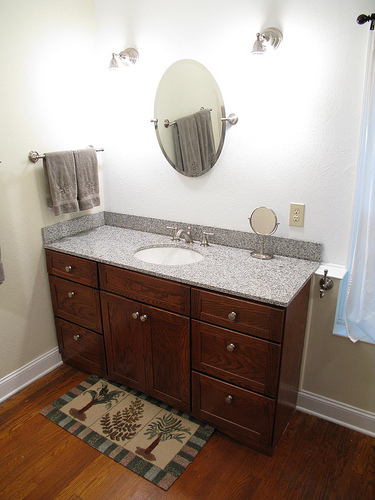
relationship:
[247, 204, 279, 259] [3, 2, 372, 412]
mirror on wall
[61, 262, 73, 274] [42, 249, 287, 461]
knob on cabinet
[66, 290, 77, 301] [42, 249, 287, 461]
knob on cabinet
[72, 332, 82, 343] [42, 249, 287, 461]
knob on cabinet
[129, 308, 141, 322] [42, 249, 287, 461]
knob on cabinet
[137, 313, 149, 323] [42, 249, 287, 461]
knob on cabinet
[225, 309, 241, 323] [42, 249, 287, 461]
knob on cabinet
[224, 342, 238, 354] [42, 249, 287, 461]
knob on cabinet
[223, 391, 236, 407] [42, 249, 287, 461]
knob on cabinet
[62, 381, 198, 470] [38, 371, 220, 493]
pattern on rug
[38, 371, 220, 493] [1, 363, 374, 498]
rug on floor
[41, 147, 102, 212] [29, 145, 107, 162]
towels on rack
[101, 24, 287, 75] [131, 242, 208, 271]
lights above sink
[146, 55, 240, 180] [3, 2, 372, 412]
mirror hanging on wall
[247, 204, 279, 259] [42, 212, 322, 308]
mirror on counter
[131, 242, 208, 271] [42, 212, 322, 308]
sink in countertop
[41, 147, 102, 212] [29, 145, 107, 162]
towels hanging on rack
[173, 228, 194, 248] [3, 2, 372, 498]
faucet in bathroom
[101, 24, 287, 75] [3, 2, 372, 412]
lights mounted to wall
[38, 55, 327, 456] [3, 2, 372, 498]
vanity in bathroom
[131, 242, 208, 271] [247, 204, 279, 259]
sink under mirror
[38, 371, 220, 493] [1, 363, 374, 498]
mat on floor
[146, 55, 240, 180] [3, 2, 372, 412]
mirror on wall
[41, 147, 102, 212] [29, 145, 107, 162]
towels on holder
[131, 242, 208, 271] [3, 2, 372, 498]
sink in bathroom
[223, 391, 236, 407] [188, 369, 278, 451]
knob on drawer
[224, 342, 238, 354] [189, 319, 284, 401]
knob on drawer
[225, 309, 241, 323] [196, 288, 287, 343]
knob on drawer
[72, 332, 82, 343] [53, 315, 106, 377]
knob on drawer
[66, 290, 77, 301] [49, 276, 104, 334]
knob on drawer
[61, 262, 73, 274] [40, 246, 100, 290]
knob on drawer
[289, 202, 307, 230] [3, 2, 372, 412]
outlet on wall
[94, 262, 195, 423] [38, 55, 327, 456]
double doors on vanity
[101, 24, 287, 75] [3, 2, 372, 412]
light fixture on wall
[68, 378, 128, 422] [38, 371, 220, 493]
palm tree on rug